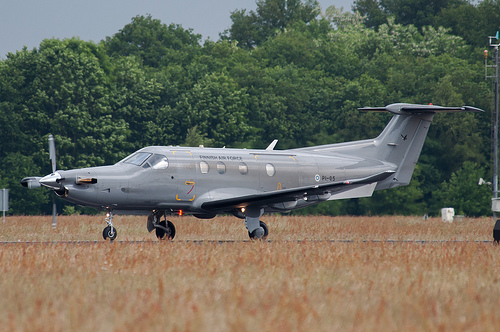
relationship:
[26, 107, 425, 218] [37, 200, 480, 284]
plane on runway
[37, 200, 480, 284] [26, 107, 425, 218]
runway below plane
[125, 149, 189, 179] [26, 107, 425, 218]
windows on plane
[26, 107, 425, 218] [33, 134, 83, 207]
plane has propeller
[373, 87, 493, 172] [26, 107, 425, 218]
tail on plane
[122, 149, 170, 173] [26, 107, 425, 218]
windows on plane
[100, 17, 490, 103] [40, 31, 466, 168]
trees in background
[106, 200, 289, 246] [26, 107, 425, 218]
landing gear on airplane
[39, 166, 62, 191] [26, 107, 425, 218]
propeller on plane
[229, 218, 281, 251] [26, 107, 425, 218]
wheel on jet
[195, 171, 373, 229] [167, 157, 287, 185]
wing by panel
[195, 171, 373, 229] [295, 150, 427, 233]
wing on back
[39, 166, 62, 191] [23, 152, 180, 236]
propeller on front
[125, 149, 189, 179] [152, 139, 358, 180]
windows on side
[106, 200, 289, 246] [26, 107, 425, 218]
landing gear for plane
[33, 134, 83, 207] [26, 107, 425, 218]
propeller on plane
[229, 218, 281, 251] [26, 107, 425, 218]
wheel on plane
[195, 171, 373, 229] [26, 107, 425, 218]
wing on plane